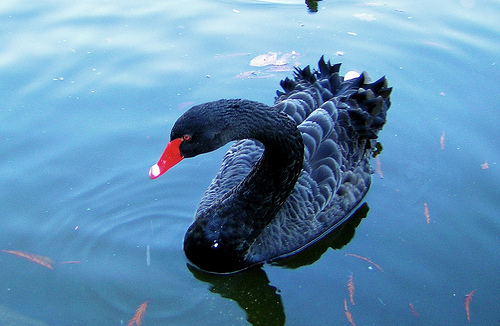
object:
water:
[1, 1, 499, 325]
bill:
[147, 137, 184, 180]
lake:
[1, 1, 500, 323]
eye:
[182, 133, 190, 140]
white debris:
[211, 241, 221, 248]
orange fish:
[124, 298, 152, 326]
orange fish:
[346, 267, 357, 306]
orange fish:
[420, 201, 431, 224]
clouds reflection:
[28, 19, 200, 88]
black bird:
[146, 54, 395, 275]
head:
[145, 98, 240, 179]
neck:
[216, 97, 306, 230]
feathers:
[170, 55, 390, 271]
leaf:
[235, 49, 303, 79]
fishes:
[438, 130, 446, 150]